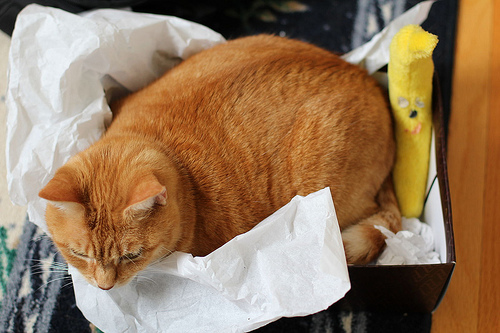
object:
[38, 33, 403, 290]
cat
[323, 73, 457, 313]
box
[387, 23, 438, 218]
toy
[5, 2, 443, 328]
paper